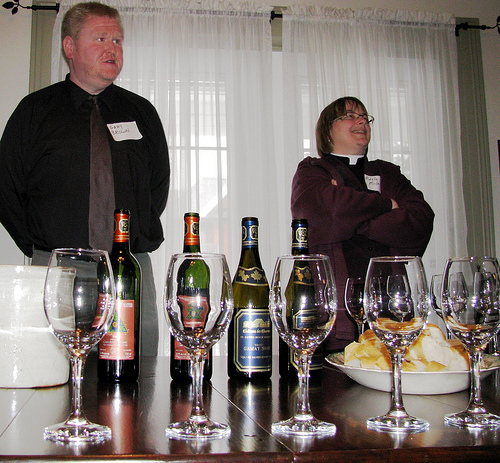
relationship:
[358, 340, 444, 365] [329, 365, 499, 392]
bread om bowl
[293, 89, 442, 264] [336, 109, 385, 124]
woman wearing glasses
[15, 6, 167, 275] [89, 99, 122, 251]
man wearing tie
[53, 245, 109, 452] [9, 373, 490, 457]
glass on top of table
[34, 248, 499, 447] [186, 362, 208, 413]
glasses has handle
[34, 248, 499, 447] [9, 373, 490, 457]
glasses on table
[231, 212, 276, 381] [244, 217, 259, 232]
bottle has top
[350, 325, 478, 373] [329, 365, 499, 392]
food inside bowl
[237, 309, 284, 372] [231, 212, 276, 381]
sticker on bottle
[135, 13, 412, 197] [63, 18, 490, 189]
curtains on window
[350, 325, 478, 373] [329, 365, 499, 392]
food on bowl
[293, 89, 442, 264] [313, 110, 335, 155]
woman has hair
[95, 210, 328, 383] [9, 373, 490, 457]
bottles on table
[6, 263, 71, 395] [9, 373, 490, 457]
canister on top of table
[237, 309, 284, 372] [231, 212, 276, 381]
sticker in front of bottle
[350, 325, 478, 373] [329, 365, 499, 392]
food in bowl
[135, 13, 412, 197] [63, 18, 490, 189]
curtains covered window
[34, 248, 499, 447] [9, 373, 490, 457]
glasses sitting on table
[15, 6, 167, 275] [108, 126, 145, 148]
man wearing name tag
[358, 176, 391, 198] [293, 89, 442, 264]
name tag on woman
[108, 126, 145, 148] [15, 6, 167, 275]
name tag on man